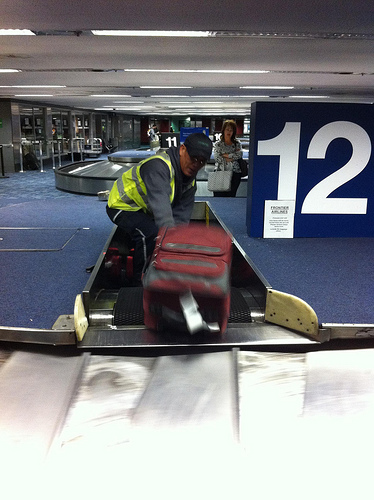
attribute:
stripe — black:
[160, 239, 221, 254]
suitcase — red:
[150, 220, 253, 350]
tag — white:
[180, 292, 200, 332]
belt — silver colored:
[1, 346, 372, 474]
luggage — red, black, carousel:
[140, 226, 232, 343]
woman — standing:
[201, 108, 253, 195]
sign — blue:
[235, 94, 372, 241]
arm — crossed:
[227, 152, 242, 158]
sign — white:
[250, 99, 372, 238]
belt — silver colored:
[233, 351, 302, 439]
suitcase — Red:
[137, 218, 229, 353]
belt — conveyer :
[115, 287, 141, 323]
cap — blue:
[178, 129, 223, 161]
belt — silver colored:
[0, 325, 372, 498]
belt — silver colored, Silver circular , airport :
[0, 346, 372, 446]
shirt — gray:
[135, 144, 199, 231]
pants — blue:
[102, 202, 168, 280]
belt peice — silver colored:
[63, 139, 134, 180]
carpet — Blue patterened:
[0, 176, 53, 199]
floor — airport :
[0, 167, 105, 204]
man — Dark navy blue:
[106, 132, 212, 285]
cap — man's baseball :
[184, 133, 213, 161]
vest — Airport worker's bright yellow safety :
[99, 155, 178, 220]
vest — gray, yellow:
[110, 156, 192, 228]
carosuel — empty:
[49, 141, 219, 204]